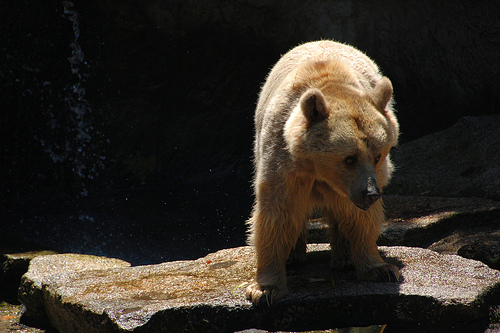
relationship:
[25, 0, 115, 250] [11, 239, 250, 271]
water drips into pool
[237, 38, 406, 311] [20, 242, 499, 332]
bear on rock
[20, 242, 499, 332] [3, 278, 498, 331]
rock on ground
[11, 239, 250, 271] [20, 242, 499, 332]
pool by rock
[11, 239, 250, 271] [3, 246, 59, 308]
pool by rock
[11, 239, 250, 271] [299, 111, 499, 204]
pool by rock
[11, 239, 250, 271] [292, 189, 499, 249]
pool by rock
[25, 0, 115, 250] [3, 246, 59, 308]
water on rock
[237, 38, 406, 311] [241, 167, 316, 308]
bear has leg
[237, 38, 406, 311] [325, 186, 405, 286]
bear has leg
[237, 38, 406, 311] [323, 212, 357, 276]
bear has leg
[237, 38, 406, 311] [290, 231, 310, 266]
bear has leg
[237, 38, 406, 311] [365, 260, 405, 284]
bear has front paw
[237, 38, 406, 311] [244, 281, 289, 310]
bear has front paw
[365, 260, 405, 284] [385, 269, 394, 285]
front paw has claw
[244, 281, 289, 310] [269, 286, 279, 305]
front paw has claw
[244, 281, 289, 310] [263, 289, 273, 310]
front paw has claw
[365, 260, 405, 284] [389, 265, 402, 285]
front paw has claw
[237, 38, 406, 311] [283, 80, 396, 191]
bear has ruff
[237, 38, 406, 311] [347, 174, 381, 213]
bear has snout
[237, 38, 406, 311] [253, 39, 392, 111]
bear has back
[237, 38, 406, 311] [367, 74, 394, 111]
bear has ear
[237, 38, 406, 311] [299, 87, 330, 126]
bear has ear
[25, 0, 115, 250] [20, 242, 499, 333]
water against rock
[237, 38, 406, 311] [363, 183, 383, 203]
bear has nose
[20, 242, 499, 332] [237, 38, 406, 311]
rock below bear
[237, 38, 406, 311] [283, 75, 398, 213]
bear has head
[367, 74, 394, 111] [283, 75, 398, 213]
ear on head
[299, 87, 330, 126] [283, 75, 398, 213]
ear on head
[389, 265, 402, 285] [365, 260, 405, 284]
claw on front paw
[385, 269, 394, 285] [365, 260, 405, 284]
claw on front paw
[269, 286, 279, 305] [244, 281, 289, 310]
claw on front paw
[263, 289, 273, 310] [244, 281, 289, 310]
claw on front paw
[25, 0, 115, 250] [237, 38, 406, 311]
water behind bear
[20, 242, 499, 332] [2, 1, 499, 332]
rock in enclosure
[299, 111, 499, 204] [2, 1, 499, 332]
rock in enclosure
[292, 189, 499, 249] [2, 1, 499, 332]
rock in enclosure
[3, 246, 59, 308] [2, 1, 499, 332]
rock in enclosure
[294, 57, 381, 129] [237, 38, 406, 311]
fur on top of bear